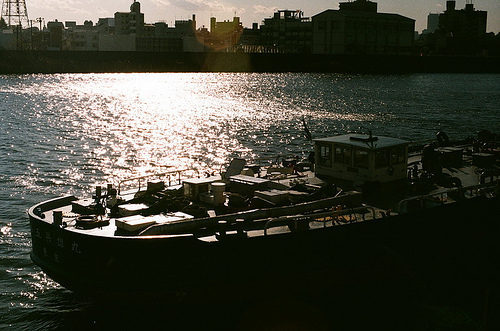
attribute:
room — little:
[310, 127, 412, 187]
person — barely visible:
[418, 137, 442, 175]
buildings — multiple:
[8, 2, 496, 62]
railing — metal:
[264, 204, 376, 227]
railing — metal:
[395, 182, 498, 209]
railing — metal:
[119, 166, 202, 197]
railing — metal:
[218, 152, 297, 168]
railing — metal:
[409, 138, 432, 149]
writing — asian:
[3, 200, 110, 292]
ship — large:
[23, 116, 495, 296]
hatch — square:
[109, 215, 162, 234]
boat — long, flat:
[112, 160, 487, 270]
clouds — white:
[156, 1, 243, 18]